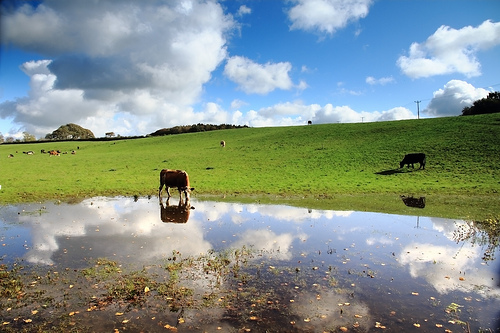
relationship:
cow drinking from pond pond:
[154, 167, 194, 202] [0, 195, 495, 328]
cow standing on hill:
[304, 117, 315, 124] [72, 105, 467, 163]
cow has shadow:
[401, 150, 427, 168] [373, 162, 412, 178]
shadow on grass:
[373, 162, 412, 178] [0, 114, 499, 216]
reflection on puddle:
[160, 201, 193, 221] [1, 190, 497, 330]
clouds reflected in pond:
[185, 50, 310, 112] [14, 212, 464, 331]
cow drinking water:
[154, 167, 194, 202] [0, 195, 498, 331]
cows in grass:
[8, 139, 86, 158] [2, 115, 499, 195]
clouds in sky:
[45, 93, 87, 121] [252, 19, 286, 49]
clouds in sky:
[79, 23, 163, 82] [330, 46, 367, 77]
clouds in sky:
[224, 54, 293, 96] [2, 3, 497, 135]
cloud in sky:
[393, 17, 499, 77] [2, 3, 497, 135]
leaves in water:
[28, 249, 495, 326] [0, 205, 492, 269]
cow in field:
[65, 144, 80, 159] [0, 110, 497, 218]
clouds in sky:
[9, 2, 230, 89] [2, 3, 497, 135]